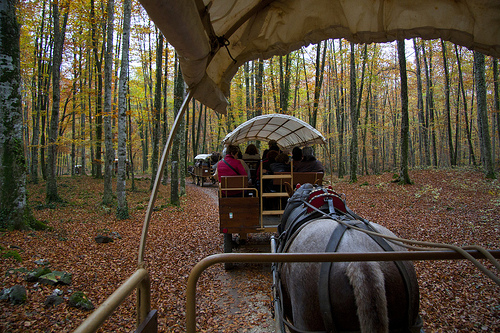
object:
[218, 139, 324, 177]
people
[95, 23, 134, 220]
tree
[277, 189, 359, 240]
harness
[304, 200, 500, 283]
rein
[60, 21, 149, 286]
leaves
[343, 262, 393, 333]
tail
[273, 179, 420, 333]
zebra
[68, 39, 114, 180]
branch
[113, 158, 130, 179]
cabin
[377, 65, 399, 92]
stem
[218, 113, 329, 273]
cart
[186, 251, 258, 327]
metal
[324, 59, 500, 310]
city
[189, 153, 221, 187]
trolley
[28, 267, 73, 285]
rock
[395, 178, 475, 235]
ground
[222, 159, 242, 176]
strap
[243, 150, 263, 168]
shirt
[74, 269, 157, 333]
rail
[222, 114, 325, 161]
canopy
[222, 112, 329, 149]
roof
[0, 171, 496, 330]
leaves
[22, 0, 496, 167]
leaves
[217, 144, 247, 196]
girl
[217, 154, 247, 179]
jacket